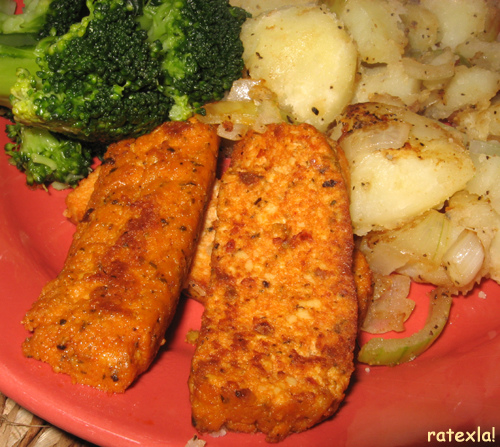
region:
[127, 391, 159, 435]
this is a plate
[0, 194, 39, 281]
the plate is red in color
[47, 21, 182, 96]
this is brocolli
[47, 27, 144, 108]
the brocolli is green in color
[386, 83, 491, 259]
these are some chips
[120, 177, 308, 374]
these are pieces of meat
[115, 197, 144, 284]
the meat is oily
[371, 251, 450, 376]
these are some spices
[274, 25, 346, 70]
the chips are white in color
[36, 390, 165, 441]
the plate is circular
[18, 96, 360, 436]
two pieces of fried fish on a coral plate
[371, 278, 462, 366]
onions on a coral plate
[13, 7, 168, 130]
green broccoli crown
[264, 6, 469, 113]
fried white potatoes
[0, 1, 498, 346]
plate of food on a coral plate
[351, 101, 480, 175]
fried white potatoes with pepper and onions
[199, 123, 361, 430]
one piece of fried fish with seasoning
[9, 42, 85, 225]
green broccoli on coral plate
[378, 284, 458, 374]
green onion with pepper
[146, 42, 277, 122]
green broccoli crown with onion, potatoes and pepper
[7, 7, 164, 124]
broccoli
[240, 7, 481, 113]
potatoes on a red plate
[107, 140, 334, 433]
fish sticks on a red plate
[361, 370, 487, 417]
part of a red plate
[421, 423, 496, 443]
a watermark on the photo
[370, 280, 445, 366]
an onion and part of a potato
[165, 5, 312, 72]
broccolli and potatoes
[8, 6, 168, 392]
broccoli and fish sticks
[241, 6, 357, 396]
potatoes and fish sticks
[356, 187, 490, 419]
potatoes and onions on a red plate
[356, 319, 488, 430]
Plate is red color.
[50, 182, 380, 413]
Three chicken fry is brown color.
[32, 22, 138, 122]
Broccoli is green color.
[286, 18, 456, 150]
Potato is fried and its on plate.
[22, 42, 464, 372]
Food is on plate.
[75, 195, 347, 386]
Fry is brown color.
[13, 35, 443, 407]
One plate of food is seen.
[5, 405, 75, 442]
Table is brown color.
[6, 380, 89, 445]
Plate is in table.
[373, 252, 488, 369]
Potato is fried with onions.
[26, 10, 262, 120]
a couple pieces of broccoli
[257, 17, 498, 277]
home-fried potatoes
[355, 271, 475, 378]
a piece of sauteed onion slightly away from the potatoes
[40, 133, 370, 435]
two pieces of fried fish on a plate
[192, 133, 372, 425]
the larger piece of greasy fried fish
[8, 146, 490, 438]
a pink plate for food.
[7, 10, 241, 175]
over-cooked green vegetables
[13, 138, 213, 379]
smaller greasy piece of fried fish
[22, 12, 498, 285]
Two different side dishes on a plate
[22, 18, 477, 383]
a fried fish with potatoes and broccoli meal